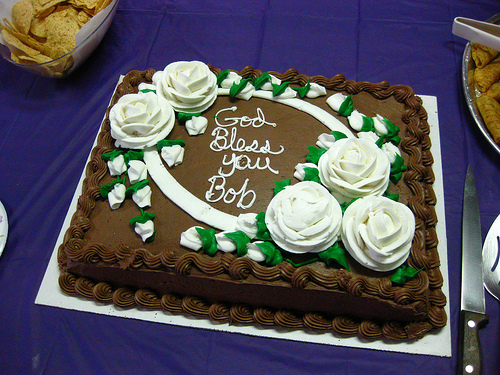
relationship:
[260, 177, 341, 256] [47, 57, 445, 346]
rose on cake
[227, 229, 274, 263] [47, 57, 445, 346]
leaves on cake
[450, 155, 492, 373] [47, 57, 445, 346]
knife next to cake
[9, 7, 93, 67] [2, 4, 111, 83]
chips in bowl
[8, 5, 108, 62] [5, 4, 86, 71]
paper under chips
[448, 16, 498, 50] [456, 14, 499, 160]
tongs in pan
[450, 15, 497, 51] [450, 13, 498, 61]
handle of tongs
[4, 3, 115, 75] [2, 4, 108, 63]
bowl of chips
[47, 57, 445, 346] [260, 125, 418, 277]
cake decorated with flowers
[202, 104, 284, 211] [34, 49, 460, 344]
writing on cake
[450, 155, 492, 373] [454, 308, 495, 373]
knife with handle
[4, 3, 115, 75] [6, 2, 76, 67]
bowl of chips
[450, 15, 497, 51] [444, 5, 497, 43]
handle of tongs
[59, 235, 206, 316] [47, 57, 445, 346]
icing on cake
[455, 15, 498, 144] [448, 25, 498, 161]
food in tin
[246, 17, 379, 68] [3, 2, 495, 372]
creases in cloth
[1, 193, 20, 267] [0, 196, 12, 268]
edge of plate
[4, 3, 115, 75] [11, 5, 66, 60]
bowl with chips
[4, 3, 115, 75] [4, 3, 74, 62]
bowl with chips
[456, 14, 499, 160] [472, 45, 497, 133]
pan with food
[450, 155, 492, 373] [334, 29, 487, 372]
knife to right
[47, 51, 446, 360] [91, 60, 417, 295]
cake with icing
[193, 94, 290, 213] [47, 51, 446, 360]
writing on cake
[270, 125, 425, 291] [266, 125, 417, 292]
group of petals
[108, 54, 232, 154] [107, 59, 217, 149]
group of petals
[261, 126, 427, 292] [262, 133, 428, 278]
flowers made of frosting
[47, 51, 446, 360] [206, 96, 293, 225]
cake with writing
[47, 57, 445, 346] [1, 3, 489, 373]
cake on table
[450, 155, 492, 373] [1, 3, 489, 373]
knife on table